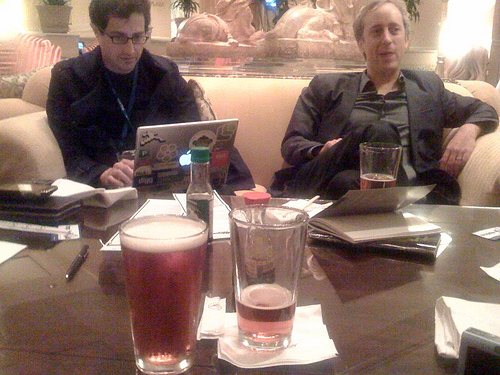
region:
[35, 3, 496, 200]
men seated on edges of tan sofa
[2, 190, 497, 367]
shiny brown table surface with papers and drinks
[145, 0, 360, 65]
statues of curved animals behind men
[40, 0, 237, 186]
man wearing eyeglasses looking at laptop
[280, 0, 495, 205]
man in dark clothes looking to side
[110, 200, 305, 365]
tall glasses with pink beverage in different amounts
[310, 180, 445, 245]
soft-cover book with cover curving open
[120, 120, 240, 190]
several stickers covering laptop cover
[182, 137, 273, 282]
covered condiment bottles behind glasses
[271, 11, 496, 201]
legs crossed and elbow on sofa arm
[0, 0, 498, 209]
two men sitting on a couch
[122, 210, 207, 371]
full glass of beer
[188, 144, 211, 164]
a green cap on a glass bottle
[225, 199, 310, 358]
almost empty glass of beer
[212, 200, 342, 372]
a glass sitting on a napkin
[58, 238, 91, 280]
black and gold ink pen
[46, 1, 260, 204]
man looking at his laptop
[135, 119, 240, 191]
stickers on the cover of laptop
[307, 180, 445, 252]
notebook with cover sticking up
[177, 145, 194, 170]
a glowing apple icon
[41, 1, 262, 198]
a man working on a laptop at a table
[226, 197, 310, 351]
a nearly empty drink glass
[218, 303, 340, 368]
a napkin under the drink glass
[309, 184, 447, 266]
a couple of notebooks stacked on the table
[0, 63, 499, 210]
a beige colored couch with two men sitting on it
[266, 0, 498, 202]
a man in a suit resting his arm on the couch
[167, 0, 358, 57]
a few statues in the distance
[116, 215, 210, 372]
a full glass of beer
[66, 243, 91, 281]
a black pen on the table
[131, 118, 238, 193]
a bunch of stickers on the man's laptop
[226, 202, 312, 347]
glass on a table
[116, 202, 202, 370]
glass on a table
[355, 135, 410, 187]
glass on a table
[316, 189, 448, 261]
books on a table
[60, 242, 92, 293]
pen on a table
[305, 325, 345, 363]
napkin on a table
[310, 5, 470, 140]
man sitting on couch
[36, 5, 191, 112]
man sitting on a couch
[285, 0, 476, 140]
man wearing black jacket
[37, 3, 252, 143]
man looking at lap top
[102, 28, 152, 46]
a man's black eyeglasses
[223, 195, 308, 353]
a tall glass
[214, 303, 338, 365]
a white napkin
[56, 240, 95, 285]
a black ink pen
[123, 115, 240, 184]
part of a laptop computer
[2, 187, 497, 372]
part of a large table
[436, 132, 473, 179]
the hand of a man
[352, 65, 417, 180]
a man's black collared shirt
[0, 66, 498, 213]
a beige couch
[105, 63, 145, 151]
a blue lanyard